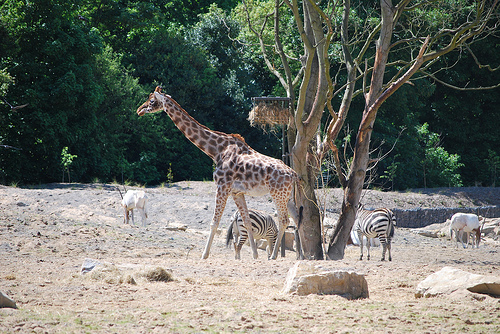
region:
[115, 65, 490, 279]
Animals in the zoo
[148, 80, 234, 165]
Giraffe with a long neck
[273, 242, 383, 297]
large rock on the ground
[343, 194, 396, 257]
zebra in the zoo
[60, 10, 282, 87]
leaves on top of trees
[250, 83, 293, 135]
Giraffe hopper in a tree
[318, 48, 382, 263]
tree with no leaves on it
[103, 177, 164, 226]
gazelle in the zoo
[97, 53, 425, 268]
several animals at the zoo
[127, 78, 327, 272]
tall brown and white giraffe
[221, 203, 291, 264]
black and white striped zebra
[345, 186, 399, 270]
black and white striped zebra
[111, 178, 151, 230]
white antelope with horns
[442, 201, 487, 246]
white antelope with horns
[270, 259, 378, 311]
large light brown rock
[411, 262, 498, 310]
large light brown rock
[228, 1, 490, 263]
large leafless tree with many branches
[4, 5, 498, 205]
dense bushy green trees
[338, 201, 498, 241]
long grey stone barrier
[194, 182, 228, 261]
the leg of a giraffe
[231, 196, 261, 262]
the leg of a giraffe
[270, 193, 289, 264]
the leg of a giraffe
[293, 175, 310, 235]
the tail of a giraffe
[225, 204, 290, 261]
a zebra standing around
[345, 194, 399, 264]
a zebra standing around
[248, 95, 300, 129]
a type of cage high on a tree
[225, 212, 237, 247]
the tail of a zebra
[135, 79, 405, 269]
a giraffe with two zebras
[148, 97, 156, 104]
the eye of a giraffe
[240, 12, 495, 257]
tree has no leaves on the lower branches.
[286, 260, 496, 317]
Two rocks are on the ground.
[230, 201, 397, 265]
The back ends of two zebras are visible.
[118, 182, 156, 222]
An animal is mostly white.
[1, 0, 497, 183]
Green trees are in the background.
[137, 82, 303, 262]
A giraffe has brown spots.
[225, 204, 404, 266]
Two zebras have black stripes.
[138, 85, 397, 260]
A giraffe is near two zebras.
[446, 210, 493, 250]
A white animal is in the sun.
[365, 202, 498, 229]
Water is near the zebra.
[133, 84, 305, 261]
An orange spotted girafe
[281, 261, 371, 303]
A large gray rock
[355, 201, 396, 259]
A zebra with head hidden behind branch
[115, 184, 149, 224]
A small white and brown animal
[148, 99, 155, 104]
Left eye of girafe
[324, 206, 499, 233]
A rock wall in distance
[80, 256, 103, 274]
A small gray rock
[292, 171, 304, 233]
Tail of a girafe